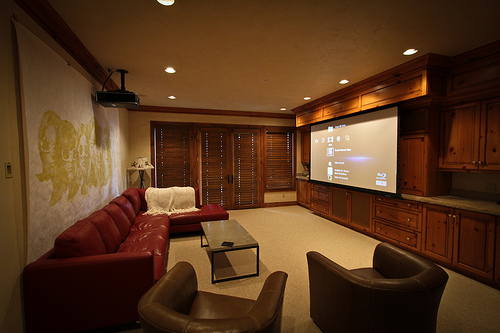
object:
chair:
[304, 242, 451, 329]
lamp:
[127, 157, 154, 189]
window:
[155, 125, 191, 187]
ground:
[398, 134, 452, 197]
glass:
[200, 219, 256, 249]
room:
[0, 10, 497, 331]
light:
[164, 67, 177, 75]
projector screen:
[308, 105, 398, 197]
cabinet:
[438, 94, 500, 169]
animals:
[37, 111, 115, 206]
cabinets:
[301, 128, 311, 163]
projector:
[95, 70, 140, 108]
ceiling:
[19, 0, 493, 113]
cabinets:
[421, 199, 497, 279]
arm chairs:
[136, 261, 289, 333]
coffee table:
[200, 219, 260, 284]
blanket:
[142, 186, 202, 216]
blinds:
[265, 127, 293, 187]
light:
[166, 95, 177, 100]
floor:
[258, 204, 318, 259]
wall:
[0, 0, 133, 331]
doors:
[203, 124, 261, 210]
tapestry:
[11, 14, 120, 264]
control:
[221, 241, 234, 247]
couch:
[23, 186, 229, 331]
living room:
[0, 0, 497, 333]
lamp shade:
[129, 155, 155, 169]